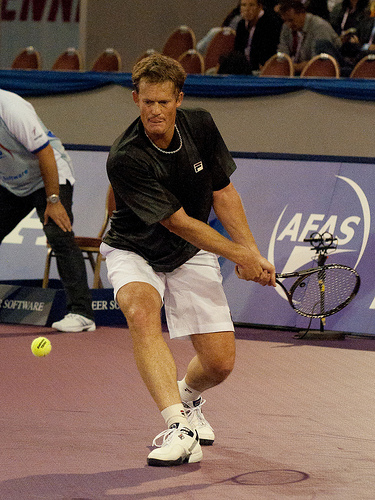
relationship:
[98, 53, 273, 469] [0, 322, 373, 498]
ear person playing at court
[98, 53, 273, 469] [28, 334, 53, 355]
ear person looking at ball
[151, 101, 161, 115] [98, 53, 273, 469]
nose of ear person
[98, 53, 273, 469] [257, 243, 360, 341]
ear person holds racket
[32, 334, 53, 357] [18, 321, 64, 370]
ball in air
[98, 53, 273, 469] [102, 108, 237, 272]
ear person wears t-shirt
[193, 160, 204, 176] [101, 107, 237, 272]
logo on shirt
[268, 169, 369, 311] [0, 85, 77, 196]
logo on shirt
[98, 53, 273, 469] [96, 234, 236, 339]
ear person wears shorts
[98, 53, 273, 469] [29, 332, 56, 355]
ear person hitting ball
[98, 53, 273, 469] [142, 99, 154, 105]
ear person has right eye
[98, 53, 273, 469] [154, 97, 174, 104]
ear person has left eye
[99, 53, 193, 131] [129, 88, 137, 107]
ear person has ear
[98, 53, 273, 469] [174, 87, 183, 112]
ear person has ear